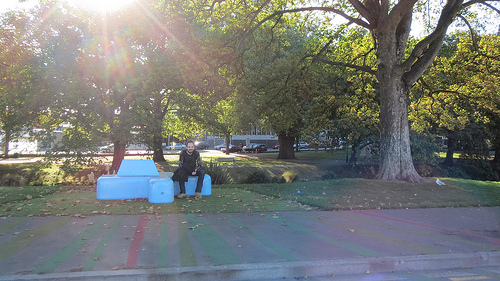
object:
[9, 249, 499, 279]
curb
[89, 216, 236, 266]
colored stripes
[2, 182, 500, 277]
ground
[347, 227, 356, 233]
leaves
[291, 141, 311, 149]
cars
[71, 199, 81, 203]
leaves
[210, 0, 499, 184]
large tree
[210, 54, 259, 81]
branches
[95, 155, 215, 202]
blue structure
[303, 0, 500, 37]
sky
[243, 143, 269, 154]
car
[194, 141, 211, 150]
car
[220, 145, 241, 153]
car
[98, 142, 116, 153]
car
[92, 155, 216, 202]
bench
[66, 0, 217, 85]
sun shining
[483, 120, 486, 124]
leaves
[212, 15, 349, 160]
tree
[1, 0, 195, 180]
tree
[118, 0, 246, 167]
tree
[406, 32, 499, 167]
tree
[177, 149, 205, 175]
shirt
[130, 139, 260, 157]
parking lot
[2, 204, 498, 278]
sidewalk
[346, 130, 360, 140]
leaves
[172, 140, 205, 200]
man